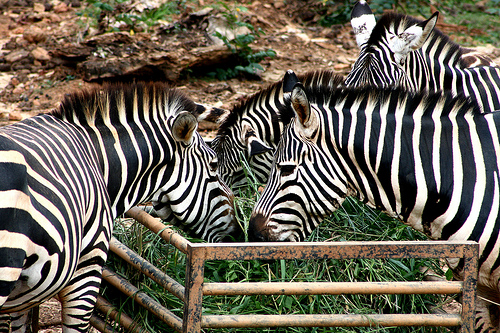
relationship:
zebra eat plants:
[263, 76, 498, 271] [222, 167, 431, 312]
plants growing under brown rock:
[211, 25, 269, 77] [52, 32, 288, 82]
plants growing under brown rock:
[78, 3, 190, 27] [52, 32, 288, 82]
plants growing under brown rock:
[303, 0, 492, 36] [52, 32, 288, 82]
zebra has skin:
[249, 76, 499, 330] [432, 115, 446, 193]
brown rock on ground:
[52, 27, 246, 72] [1, 1, 361, 141]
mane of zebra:
[53, 80, 165, 130] [249, 76, 499, 330]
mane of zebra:
[396, 8, 459, 63] [0, 72, 240, 326]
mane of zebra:
[231, 69, 476, 117] [207, 67, 346, 199]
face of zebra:
[161, 105, 245, 241] [0, 72, 240, 326]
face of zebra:
[248, 95, 346, 240] [249, 76, 499, 330]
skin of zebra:
[402, 108, 412, 181] [245, 72, 498, 242]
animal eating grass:
[0, 81, 237, 333] [134, 198, 450, 328]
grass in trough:
[206, 260, 418, 279] [112, 194, 478, 331]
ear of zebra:
[288, 82, 312, 129] [249, 76, 499, 330]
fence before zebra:
[100, 207, 483, 326] [263, 76, 498, 271]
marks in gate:
[463, 274, 478, 306] [104, 200, 497, 331]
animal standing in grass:
[0, 81, 237, 333] [206, 260, 421, 281]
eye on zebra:
[272, 155, 304, 178] [238, 70, 486, 267]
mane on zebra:
[299, 85, 476, 117] [244, 80, 499, 295]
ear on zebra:
[291, 82, 311, 127] [2, 65, 259, 328]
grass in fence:
[206, 229, 409, 311] [100, 175, 483, 325]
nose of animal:
[223, 211, 244, 241] [33, 94, 301, 278]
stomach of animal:
[20, 189, 118, 332] [0, 81, 237, 333]